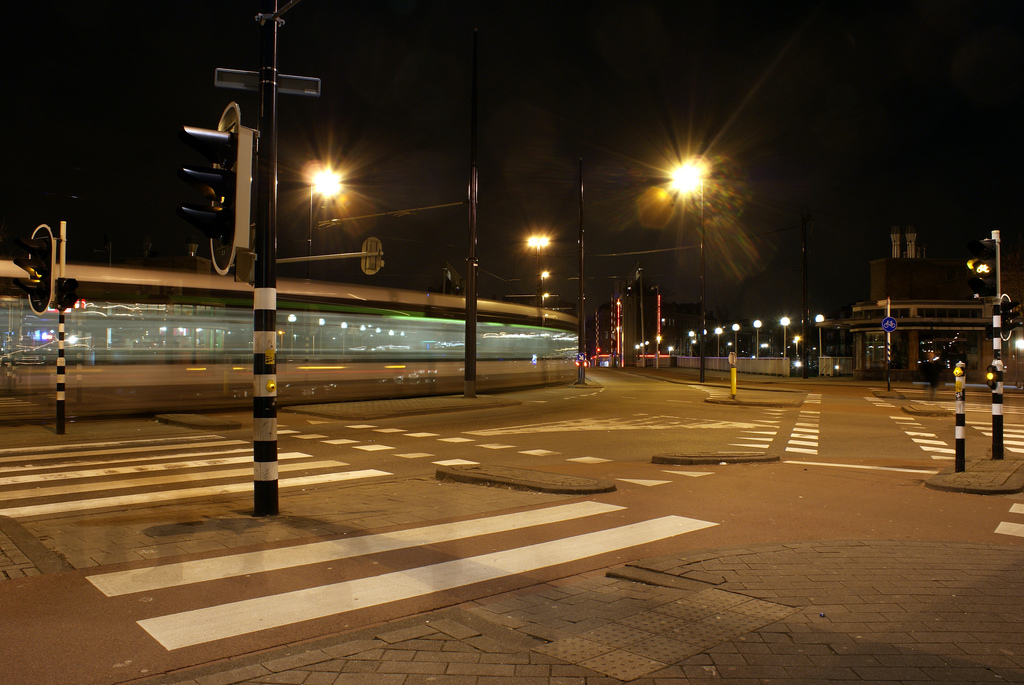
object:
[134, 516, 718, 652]
line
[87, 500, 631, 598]
line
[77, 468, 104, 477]
line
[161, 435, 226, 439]
line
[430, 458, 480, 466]
line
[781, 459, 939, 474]
line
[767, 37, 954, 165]
sky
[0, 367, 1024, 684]
road